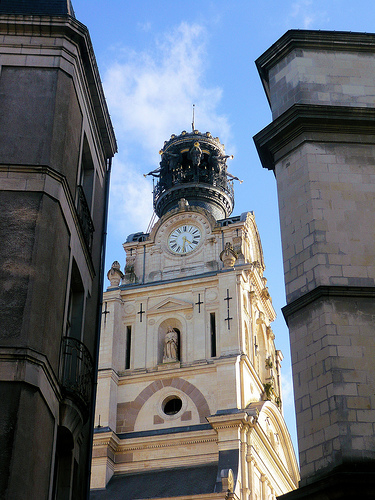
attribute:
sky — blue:
[123, 37, 210, 73]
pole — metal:
[174, 101, 205, 135]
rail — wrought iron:
[54, 334, 99, 419]